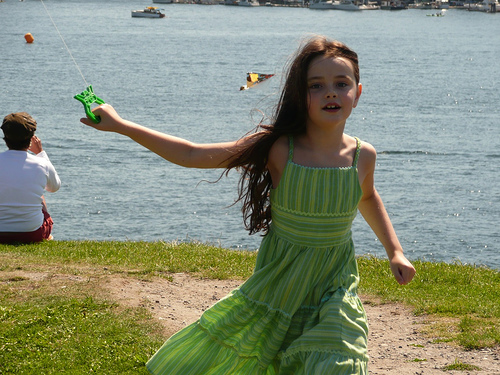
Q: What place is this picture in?
A: It is at the lake.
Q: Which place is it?
A: It is a lake.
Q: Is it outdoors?
A: Yes, it is outdoors.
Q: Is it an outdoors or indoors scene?
A: It is outdoors.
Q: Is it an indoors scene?
A: No, it is outdoors.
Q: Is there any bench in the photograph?
A: No, there are no benches.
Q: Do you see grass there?
A: Yes, there is grass.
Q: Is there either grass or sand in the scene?
A: Yes, there is grass.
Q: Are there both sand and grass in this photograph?
A: No, there is grass but no sand.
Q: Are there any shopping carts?
A: No, there are no shopping carts.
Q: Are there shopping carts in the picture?
A: No, there are no shopping carts.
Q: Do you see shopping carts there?
A: No, there are no shopping carts.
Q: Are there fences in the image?
A: No, there are no fences.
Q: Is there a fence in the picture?
A: No, there are no fences.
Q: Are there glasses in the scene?
A: No, there are no glasses.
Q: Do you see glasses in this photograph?
A: No, there are no glasses.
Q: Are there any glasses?
A: No, there are no glasses.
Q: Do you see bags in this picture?
A: No, there are no bags.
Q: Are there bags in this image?
A: No, there are no bags.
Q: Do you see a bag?
A: No, there are no bags.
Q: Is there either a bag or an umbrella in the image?
A: No, there are no bags or umbrellas.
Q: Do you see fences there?
A: No, there are no fences.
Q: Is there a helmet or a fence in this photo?
A: No, there are no fences or helmets.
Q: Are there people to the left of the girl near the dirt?
A: Yes, there is a person to the left of the girl.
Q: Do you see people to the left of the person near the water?
A: Yes, there is a person to the left of the girl.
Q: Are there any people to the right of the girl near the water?
A: No, the person is to the left of the girl.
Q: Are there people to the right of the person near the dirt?
A: No, the person is to the left of the girl.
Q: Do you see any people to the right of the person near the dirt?
A: No, the person is to the left of the girl.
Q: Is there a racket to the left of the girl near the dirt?
A: No, there is a person to the left of the girl.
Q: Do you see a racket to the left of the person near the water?
A: No, there is a person to the left of the girl.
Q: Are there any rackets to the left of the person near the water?
A: No, there is a person to the left of the girl.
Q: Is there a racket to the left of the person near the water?
A: No, there is a person to the left of the girl.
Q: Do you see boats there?
A: Yes, there is a boat.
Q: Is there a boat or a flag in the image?
A: Yes, there is a boat.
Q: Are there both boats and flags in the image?
A: No, there is a boat but no flags.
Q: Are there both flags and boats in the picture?
A: No, there is a boat but no flags.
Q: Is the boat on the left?
A: Yes, the boat is on the left of the image.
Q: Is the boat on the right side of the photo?
A: No, the boat is on the left of the image.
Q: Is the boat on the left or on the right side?
A: The boat is on the left of the image.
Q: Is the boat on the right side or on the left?
A: The boat is on the left of the image.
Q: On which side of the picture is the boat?
A: The boat is on the left of the image.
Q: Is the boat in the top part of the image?
A: Yes, the boat is in the top of the image.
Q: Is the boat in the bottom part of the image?
A: No, the boat is in the top of the image.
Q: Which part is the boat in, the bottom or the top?
A: The boat is in the top of the image.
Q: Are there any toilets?
A: No, there are no toilets.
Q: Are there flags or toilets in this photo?
A: No, there are no toilets or flags.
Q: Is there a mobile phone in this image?
A: No, there are no cell phones.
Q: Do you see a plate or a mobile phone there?
A: No, there are no cell phones or plates.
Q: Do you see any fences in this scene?
A: No, there are no fences.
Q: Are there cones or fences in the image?
A: No, there are no fences or cones.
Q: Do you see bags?
A: No, there are no bags.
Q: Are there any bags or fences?
A: No, there are no bags or fences.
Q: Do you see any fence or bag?
A: No, there are no bags or fences.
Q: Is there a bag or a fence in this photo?
A: No, there are no bags or fences.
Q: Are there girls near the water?
A: Yes, there is a girl near the water.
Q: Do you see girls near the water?
A: Yes, there is a girl near the water.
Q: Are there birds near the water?
A: No, there is a girl near the water.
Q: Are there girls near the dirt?
A: Yes, there is a girl near the dirt.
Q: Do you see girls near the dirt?
A: Yes, there is a girl near the dirt.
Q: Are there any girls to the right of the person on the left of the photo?
A: Yes, there is a girl to the right of the person.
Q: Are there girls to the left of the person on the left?
A: No, the girl is to the right of the person.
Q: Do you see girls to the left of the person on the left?
A: No, the girl is to the right of the person.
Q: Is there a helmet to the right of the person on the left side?
A: No, there is a girl to the right of the person.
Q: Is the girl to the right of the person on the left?
A: Yes, the girl is to the right of the person.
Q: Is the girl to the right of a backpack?
A: No, the girl is to the right of the person.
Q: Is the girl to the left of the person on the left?
A: No, the girl is to the right of the person.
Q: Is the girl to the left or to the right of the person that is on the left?
A: The girl is to the right of the person.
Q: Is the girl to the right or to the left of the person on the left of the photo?
A: The girl is to the right of the person.